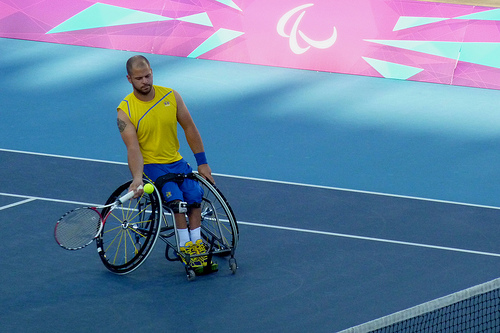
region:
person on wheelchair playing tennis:
[50, 53, 247, 281]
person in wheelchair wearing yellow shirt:
[116, 58, 222, 278]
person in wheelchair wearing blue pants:
[113, 52, 221, 276]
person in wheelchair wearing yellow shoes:
[112, 55, 224, 277]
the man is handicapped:
[62, 74, 306, 281]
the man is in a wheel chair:
[97, 118, 295, 312]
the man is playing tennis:
[60, 177, 201, 264]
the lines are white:
[305, 217, 437, 289]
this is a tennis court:
[41, 40, 453, 274]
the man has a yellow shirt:
[72, 78, 206, 175]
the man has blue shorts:
[142, 160, 253, 237]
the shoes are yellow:
[131, 213, 279, 280]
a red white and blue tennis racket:
[51, 182, 144, 250]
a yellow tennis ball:
[141, 180, 153, 193]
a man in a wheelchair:
[97, 55, 238, 279]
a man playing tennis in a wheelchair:
[53, 55, 240, 280]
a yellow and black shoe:
[181, 242, 201, 272]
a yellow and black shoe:
[195, 240, 220, 271]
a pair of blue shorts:
[142, 161, 204, 205]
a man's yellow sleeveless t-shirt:
[115, 85, 182, 165]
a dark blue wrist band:
[191, 149, 207, 165]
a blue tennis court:
[0, 143, 498, 331]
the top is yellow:
[120, 90, 185, 171]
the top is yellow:
[114, 92, 181, 174]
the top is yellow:
[114, 85, 198, 176]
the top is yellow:
[112, 88, 190, 174]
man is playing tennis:
[32, 40, 254, 282]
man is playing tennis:
[37, 51, 248, 291]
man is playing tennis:
[37, 46, 254, 305]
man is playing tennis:
[37, 43, 252, 285]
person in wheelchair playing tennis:
[46, 51, 243, 281]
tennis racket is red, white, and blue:
[52, 182, 144, 250]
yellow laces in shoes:
[173, 238, 215, 271]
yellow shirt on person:
[116, 81, 183, 165]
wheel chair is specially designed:
[94, 165, 239, 283]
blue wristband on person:
[193, 148, 206, 165]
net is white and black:
[315, 271, 499, 331]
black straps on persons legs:
[155, 170, 205, 211]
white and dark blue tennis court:
[1, 143, 499, 331]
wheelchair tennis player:
[90, 59, 250, 280]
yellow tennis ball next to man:
[146, 180, 154, 197]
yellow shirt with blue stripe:
[123, 92, 191, 160]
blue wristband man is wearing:
[191, 147, 210, 164]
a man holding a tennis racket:
[53, 170, 148, 256]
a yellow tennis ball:
[140, 177, 159, 194]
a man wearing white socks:
[170, 223, 205, 245]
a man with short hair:
[120, 51, 149, 80]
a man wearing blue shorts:
[148, 159, 202, 206]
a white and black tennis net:
[390, 281, 498, 331]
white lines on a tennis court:
[290, 166, 491, 271]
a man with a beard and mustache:
[134, 81, 155, 96]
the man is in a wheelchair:
[96, 55, 240, 280]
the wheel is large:
[99, 176, 163, 274]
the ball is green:
[143, 182, 153, 194]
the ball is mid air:
[142, 180, 152, 194]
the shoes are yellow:
[178, 240, 215, 268]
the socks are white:
[176, 225, 201, 247]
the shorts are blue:
[140, 155, 205, 204]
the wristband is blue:
[191, 148, 207, 163]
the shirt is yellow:
[117, 86, 182, 163]